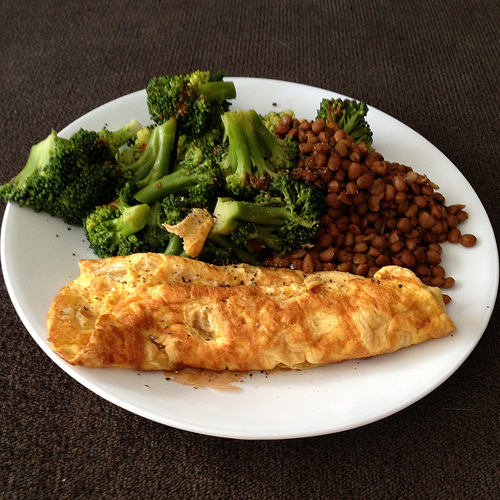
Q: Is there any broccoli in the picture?
A: Yes, there is broccoli.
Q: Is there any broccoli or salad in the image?
A: Yes, there is broccoli.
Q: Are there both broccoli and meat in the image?
A: No, there is broccoli but no meat.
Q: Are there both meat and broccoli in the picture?
A: No, there is broccoli but no meat.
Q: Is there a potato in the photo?
A: No, there are no potatoes.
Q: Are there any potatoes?
A: No, there are no potatoes.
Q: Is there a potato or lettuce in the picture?
A: No, there are no potatoes or lettuce.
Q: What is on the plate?
A: The broccoli is on the plate.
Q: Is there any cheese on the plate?
A: No, there is broccoli on the plate.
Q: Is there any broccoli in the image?
A: Yes, there is broccoli.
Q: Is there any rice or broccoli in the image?
A: Yes, there is broccoli.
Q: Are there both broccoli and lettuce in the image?
A: No, there is broccoli but no lettuce.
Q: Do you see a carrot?
A: No, there are no carrots.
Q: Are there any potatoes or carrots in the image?
A: No, there are no carrots or potatoes.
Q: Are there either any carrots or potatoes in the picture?
A: No, there are no carrots or potatoes.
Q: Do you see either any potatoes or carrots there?
A: No, there are no carrots or potatoes.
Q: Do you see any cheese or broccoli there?
A: Yes, there is broccoli.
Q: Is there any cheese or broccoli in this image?
A: Yes, there is broccoli.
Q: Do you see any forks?
A: No, there are no forks.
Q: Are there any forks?
A: No, there are no forks.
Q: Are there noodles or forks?
A: No, there are no forks or noodles.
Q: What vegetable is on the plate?
A: The vegetable is broccoli.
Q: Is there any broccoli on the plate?
A: Yes, there is broccoli on the plate.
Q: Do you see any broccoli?
A: Yes, there is broccoli.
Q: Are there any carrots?
A: No, there are no carrots.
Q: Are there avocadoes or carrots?
A: No, there are no carrots or avocadoes.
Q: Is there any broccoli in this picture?
A: Yes, there is broccoli.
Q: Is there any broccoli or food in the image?
A: Yes, there is broccoli.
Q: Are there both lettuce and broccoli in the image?
A: No, there is broccoli but no lettuce.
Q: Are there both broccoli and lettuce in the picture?
A: No, there is broccoli but no lettuce.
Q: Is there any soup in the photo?
A: No, there is no soup.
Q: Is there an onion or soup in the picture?
A: No, there are no soup or onions.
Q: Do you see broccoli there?
A: Yes, there is broccoli.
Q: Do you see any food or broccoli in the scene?
A: Yes, there is broccoli.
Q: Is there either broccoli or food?
A: Yes, there is broccoli.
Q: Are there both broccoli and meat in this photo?
A: No, there is broccoli but no meat.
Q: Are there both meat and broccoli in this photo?
A: No, there is broccoli but no meat.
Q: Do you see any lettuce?
A: No, there is no lettuce.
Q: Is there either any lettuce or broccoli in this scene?
A: Yes, there is broccoli.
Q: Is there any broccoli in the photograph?
A: Yes, there is broccoli.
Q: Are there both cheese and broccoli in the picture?
A: No, there is broccoli but no cheese.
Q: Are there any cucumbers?
A: No, there are no cucumbers.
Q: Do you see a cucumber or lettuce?
A: No, there are no cucumbers or lettuce.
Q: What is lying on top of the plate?
A: The omelette is lying on top of the plate.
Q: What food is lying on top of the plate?
A: The food is omelette.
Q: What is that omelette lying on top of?
A: The omelette is lying on top of the plate.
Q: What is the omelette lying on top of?
A: The omelette is lying on top of the plate.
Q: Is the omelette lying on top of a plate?
A: Yes, the omelette is lying on top of a plate.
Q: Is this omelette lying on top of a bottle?
A: No, the omelette is lying on top of a plate.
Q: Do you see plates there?
A: Yes, there is a plate.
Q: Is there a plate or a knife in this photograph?
A: Yes, there is a plate.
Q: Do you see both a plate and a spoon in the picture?
A: No, there is a plate but no spoons.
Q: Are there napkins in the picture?
A: No, there are no napkins.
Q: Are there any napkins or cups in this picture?
A: No, there are no napkins or cups.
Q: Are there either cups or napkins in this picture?
A: No, there are no napkins or cups.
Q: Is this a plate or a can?
A: This is a plate.